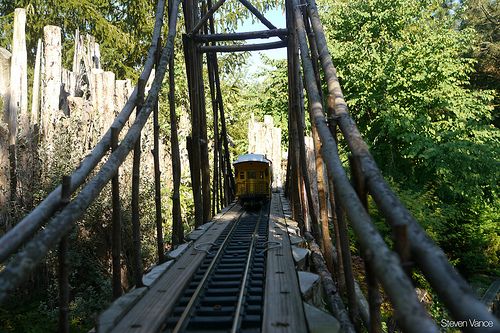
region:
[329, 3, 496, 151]
The trees are green.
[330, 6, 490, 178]
The trees are in the woods.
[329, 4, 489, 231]
The leaves indicate that it is summer.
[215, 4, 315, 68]
The sky is clear.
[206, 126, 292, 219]
A yellow train.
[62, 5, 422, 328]
A wooden bridge.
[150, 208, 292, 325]
Train tracks.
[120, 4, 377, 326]
A yellow train crossing a wooden bridge.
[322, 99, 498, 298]
The trees create shade.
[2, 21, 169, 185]
Tree trunks.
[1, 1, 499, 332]
Wooden bridge with train tracks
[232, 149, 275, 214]
The train is yellow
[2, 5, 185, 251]
Large wood wall to the left of the bridge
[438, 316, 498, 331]
Watermark is by Steven Vance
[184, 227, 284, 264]
There are ropes on the tracks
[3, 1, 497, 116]
the sky is blue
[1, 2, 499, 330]
Green leaves on trees surround the bridge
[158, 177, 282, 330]
Train tracks are metal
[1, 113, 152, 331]
Tree to left of bridge has brown leaves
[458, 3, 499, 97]
Tree on top right has brown leaves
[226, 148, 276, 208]
yellow train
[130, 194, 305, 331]
dark train tracks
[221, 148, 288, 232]
train on the train tracks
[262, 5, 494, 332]
green trees along the side of the bridge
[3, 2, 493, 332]
dark bridge with train tracks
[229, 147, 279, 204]
train with only one car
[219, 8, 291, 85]
clear, blue patch of sky poking through the tree tops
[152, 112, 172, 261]
steel rod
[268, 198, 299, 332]
wooden plank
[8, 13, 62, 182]
light brown tree trunks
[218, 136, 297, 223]
a train caboose on a track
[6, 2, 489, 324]
a train on a suspension bridge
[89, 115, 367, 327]
a train on the tracks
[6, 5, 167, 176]
a large wall made of logs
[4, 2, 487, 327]
a train in the forest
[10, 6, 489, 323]
a train moving over a bridge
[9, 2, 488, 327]
a train caboose on a bridge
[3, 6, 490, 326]
train bridge over water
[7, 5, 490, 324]
train moving down the tracks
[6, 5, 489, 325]
train parked on a bridge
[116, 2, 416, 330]
A train crossing a wooden bridge.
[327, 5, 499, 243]
Lots of trees in the background.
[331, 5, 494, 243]
It is summer.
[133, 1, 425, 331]
The bridge is narrow.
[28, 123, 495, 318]
The bottom is shaded from the sun.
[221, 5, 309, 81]
The sky is bright and clear.